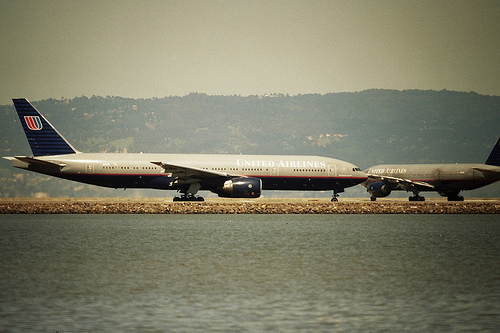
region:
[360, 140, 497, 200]
A large united airlines plane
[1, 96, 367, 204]
A large united airlines plane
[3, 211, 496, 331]
A body of water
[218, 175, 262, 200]
An engine on a plane's right wing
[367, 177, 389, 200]
An engine on a plane's left wing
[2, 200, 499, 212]
A rocky shore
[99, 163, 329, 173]
Passenger windows on a plane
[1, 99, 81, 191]
The tail wing of a plane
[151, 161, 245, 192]
The right wing of a plane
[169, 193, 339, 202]
The landing gear of a plane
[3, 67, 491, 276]
2 planes on airstrip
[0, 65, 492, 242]
one plane smaller than the other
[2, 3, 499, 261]
air strip with 2 planes in middle of water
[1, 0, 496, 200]
overcast, dusty sky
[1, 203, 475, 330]
ripples in dark water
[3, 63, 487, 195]
hillside behind airstrip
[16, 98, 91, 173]
united Air logo on plane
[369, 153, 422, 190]
United States logo on plane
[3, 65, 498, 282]
grey planes with white writing and blue bottoms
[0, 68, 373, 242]
red stripe on plane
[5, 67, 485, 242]
two jets on a runway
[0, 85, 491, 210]
two commerical jets on a runway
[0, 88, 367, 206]
a jet on a runway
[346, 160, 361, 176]
the cockpit on a jet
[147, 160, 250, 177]
the wing on a jet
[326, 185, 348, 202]
the nose-gear on a jet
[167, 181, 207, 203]
the rear landing gear on a jet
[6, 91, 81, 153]
the tail-fin on a jet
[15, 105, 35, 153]
the rudder on a jet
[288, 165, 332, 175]
the passenger windows on a jet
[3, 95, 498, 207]
Two airplanes near each other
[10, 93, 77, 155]
Tail of a plane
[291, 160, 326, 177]
Windows on side of the plane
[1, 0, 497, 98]
The sky appears overcast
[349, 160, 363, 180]
Windows on front of the plane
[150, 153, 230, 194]
A wing on a plane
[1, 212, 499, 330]
Blue and calm water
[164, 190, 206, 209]
Wheels under a plane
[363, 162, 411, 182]
White writing on side of the plane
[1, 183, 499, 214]
Airplanes on the grass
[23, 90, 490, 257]
two planes in the photo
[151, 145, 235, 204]
wing of the plane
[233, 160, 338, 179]
windows on the side of the plane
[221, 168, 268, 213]
engine on side of plane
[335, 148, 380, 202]
nose of the plane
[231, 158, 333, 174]
words on the side of the plane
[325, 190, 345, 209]
wheel on the bottom of the plane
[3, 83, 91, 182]
tail of the plane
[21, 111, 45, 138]
red and blue logo on plane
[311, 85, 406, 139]
trees in the distance